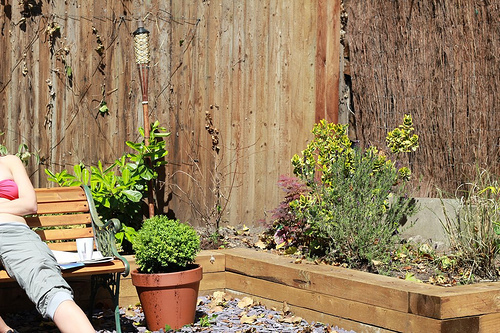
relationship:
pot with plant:
[126, 262, 208, 332] [125, 212, 202, 274]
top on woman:
[0, 175, 23, 203] [0, 147, 103, 332]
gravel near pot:
[1, 289, 376, 333] [126, 262, 208, 332]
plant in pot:
[125, 212, 202, 274] [126, 262, 208, 332]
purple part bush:
[271, 175, 309, 241] [261, 174, 321, 248]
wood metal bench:
[1, 183, 124, 281] [0, 178, 133, 332]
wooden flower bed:
[92, 238, 499, 329] [104, 245, 499, 331]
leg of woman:
[1, 218, 102, 332] [0, 147, 103, 332]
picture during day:
[1, 1, 499, 329] [1, 0, 500, 331]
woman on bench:
[0, 147, 103, 332] [0, 178, 133, 332]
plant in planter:
[125, 212, 202, 274] [126, 261, 210, 331]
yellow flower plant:
[312, 117, 344, 149] [286, 112, 424, 220]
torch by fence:
[123, 18, 169, 241] [1, 0, 342, 229]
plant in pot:
[111, 212, 203, 274] [126, 262, 208, 332]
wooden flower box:
[92, 238, 499, 329] [109, 228, 498, 332]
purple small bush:
[271, 175, 309, 241] [261, 174, 321, 248]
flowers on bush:
[277, 113, 433, 184] [281, 114, 421, 233]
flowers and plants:
[277, 113, 433, 184] [41, 102, 500, 292]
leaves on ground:
[198, 286, 304, 331] [1, 283, 379, 332]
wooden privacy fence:
[1, 0, 348, 246] [1, 0, 342, 229]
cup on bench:
[73, 236, 97, 263] [0, 178, 133, 332]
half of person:
[1, 146, 101, 333] [0, 147, 98, 331]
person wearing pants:
[0, 147, 98, 331] [1, 219, 77, 323]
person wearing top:
[0, 147, 98, 331] [0, 175, 23, 203]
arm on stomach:
[0, 153, 38, 217] [0, 195, 29, 230]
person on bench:
[0, 147, 98, 331] [0, 178, 133, 332]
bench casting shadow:
[0, 178, 133, 332] [1, 281, 143, 332]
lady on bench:
[0, 147, 103, 332] [0, 178, 133, 332]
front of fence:
[1, 0, 348, 238] [1, 0, 342, 229]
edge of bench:
[0, 256, 128, 289] [0, 178, 133, 332]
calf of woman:
[48, 298, 103, 332] [0, 147, 103, 332]